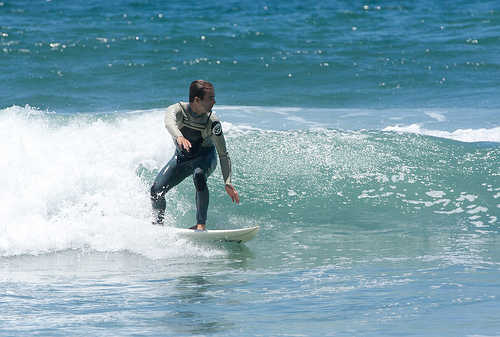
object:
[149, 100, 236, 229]
suit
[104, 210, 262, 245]
board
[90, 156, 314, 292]
water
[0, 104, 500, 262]
wave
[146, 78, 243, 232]
man